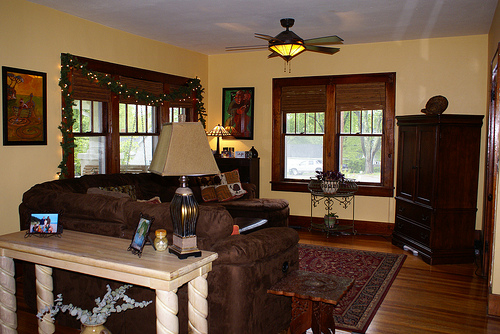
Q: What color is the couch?
A: Brown.